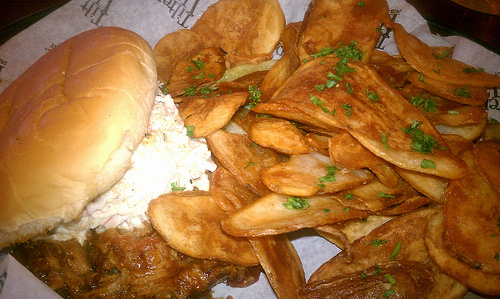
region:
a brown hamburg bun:
[0, 16, 160, 248]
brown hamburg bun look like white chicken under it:
[1, 22, 216, 244]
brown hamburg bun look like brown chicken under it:
[5, 225, 260, 295]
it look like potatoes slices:
[150, 0, 495, 295]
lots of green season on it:
[151, 0, 496, 295]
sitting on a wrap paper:
[0, 0, 495, 295]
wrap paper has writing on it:
[0, 0, 490, 295]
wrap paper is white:
[0, 0, 497, 297]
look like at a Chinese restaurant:
[0, 0, 498, 293]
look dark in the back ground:
[0, 0, 499, 70]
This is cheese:
[135, 121, 224, 223]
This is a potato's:
[255, 56, 452, 212]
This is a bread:
[3, 37, 216, 277]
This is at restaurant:
[28, 23, 481, 296]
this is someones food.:
[20, 8, 485, 298]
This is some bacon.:
[30, 224, 281, 297]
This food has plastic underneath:
[11, 7, 334, 239]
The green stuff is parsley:
[285, 23, 470, 200]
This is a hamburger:
[18, 28, 264, 296]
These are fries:
[216, 38, 496, 256]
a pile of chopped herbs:
[316, 35, 365, 97]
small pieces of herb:
[316, 41, 377, 96]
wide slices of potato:
[224, 36, 434, 227]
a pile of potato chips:
[249, 68, 444, 233]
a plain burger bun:
[3, 16, 200, 248]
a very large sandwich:
[11, 26, 232, 291]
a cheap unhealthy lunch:
[29, 33, 482, 291]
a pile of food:
[108, 121, 208, 214]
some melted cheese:
[70, 244, 185, 296]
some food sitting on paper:
[16, 3, 495, 249]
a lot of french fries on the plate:
[172, 3, 494, 296]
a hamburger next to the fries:
[1, 38, 218, 291]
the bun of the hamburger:
[3, 30, 155, 261]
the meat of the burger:
[38, 227, 205, 294]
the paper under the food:
[7, 7, 201, 51]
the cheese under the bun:
[76, 90, 200, 237]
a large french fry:
[438, 143, 496, 296]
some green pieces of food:
[313, 42, 364, 124]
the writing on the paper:
[161, 1, 200, 33]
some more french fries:
[211, 70, 326, 232]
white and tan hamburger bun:
[7, 24, 152, 250]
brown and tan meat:
[74, 227, 185, 297]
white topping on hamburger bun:
[161, 117, 203, 192]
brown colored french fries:
[159, 5, 281, 123]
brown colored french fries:
[183, 92, 313, 178]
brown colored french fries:
[138, 188, 299, 290]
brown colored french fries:
[323, 161, 450, 286]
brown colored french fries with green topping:
[290, 28, 457, 194]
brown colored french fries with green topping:
[321, 157, 491, 283]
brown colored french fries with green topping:
[345, 13, 486, 181]